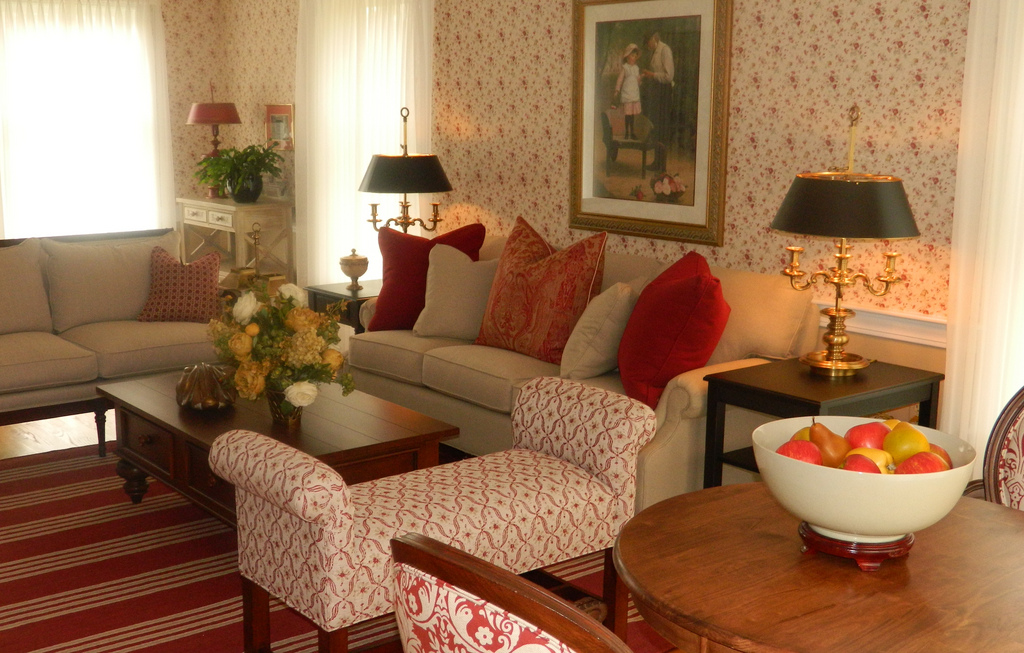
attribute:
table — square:
[704, 351, 944, 505]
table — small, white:
[319, 211, 404, 322]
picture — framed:
[571, 1, 740, 254]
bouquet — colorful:
[215, 281, 367, 416]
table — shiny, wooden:
[89, 351, 465, 509]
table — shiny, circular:
[624, 458, 955, 647]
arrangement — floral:
[167, 251, 364, 429]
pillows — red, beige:
[353, 212, 727, 375]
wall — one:
[413, 39, 960, 362]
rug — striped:
[22, 476, 223, 649]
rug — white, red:
[24, 486, 245, 642]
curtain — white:
[275, 13, 440, 312]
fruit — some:
[761, 407, 954, 485]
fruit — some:
[778, 415, 960, 480]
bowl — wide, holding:
[748, 398, 982, 582]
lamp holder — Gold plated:
[803, 312, 877, 379]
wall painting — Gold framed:
[537, 0, 766, 264]